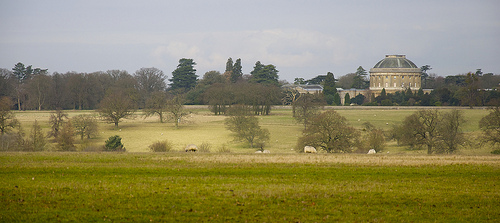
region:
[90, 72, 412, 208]
this are trees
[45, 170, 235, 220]
this is green grass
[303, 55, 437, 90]
this is someones home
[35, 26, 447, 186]
what a nice shot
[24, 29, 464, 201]
this a lovely short indeed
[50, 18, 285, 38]
this is an outdoor photo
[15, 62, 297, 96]
this is vegetation growing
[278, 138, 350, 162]
this are animals grazing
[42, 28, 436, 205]
i love this nature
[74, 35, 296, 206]
i love it nice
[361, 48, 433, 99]
building with dome roof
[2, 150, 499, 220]
large lawn with green grass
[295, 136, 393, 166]
white cows eating grass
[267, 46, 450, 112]
large white brick building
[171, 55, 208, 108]
large evergreen tree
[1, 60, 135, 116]
trees in the fall with no leaves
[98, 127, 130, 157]
small evergreen tree int he fall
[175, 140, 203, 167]
white sheep grazing on grass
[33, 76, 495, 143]
large courtyard with green grass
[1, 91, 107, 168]
trees in the fall with no leaves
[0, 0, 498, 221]
this is a sunny clear day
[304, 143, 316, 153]
a white cow is grazing in the field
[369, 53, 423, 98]
a round observatory looking building beyond the open field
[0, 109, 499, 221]
a field with grazing animals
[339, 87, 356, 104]
an archway entrance to the building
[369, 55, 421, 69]
the roof is gray in color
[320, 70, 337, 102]
evergreen pine trees are around the round building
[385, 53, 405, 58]
a flat structure is on the top of the roof of the round building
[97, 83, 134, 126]
deciduous trees have lost their leeves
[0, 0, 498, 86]
white clouds in the blue sky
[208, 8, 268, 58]
the sky is covered by clouds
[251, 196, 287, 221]
the plants are green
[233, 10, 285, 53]
the clouds are grey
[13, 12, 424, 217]
it is sunn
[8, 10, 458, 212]
it is in a field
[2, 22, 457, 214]
it is an outdoor scene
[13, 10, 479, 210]
it is a daytime scene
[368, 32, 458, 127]
the building is brown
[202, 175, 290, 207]
the grass is short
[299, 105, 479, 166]
trees are dry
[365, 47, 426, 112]
a construction used to pray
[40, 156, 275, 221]
the green grass on ground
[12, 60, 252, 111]
the long green trees in forest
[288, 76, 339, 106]
the houses constructed to live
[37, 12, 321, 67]
the blue sky with cool air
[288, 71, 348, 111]
the houses to live for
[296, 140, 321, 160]
cows eating grass for survival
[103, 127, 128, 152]
the small green tree with bushes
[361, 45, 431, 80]
the roof top of the construction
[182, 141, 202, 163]
the goat eating grass for survival